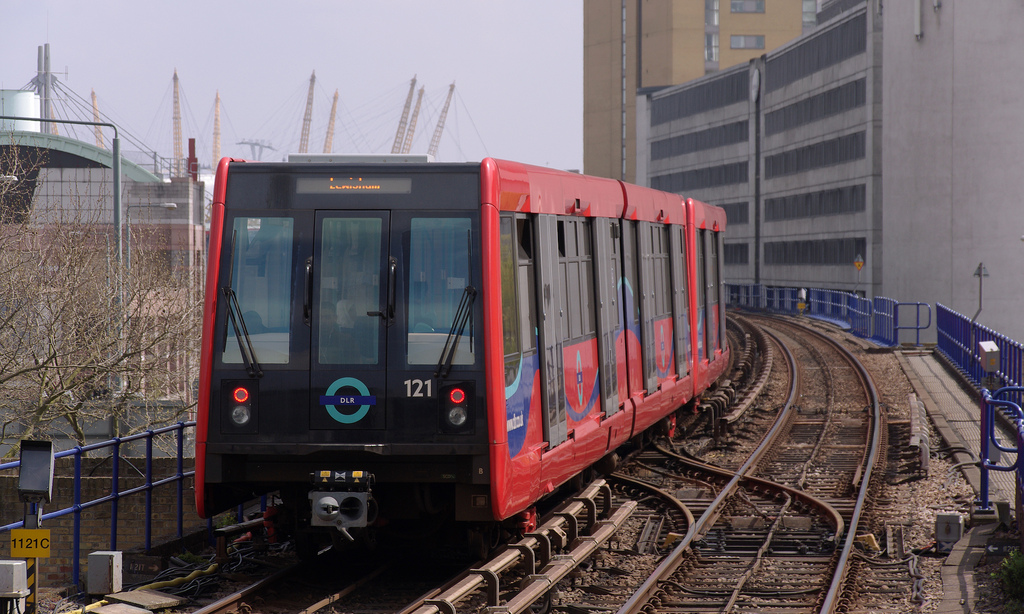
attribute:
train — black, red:
[253, 184, 733, 527]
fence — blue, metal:
[16, 367, 245, 589]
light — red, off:
[406, 367, 474, 419]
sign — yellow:
[9, 524, 63, 566]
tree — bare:
[9, 198, 222, 442]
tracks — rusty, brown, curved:
[704, 310, 858, 587]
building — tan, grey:
[587, 7, 790, 217]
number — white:
[382, 350, 444, 402]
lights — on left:
[222, 375, 491, 441]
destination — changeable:
[317, 164, 397, 204]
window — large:
[228, 225, 296, 369]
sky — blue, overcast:
[65, 1, 574, 168]